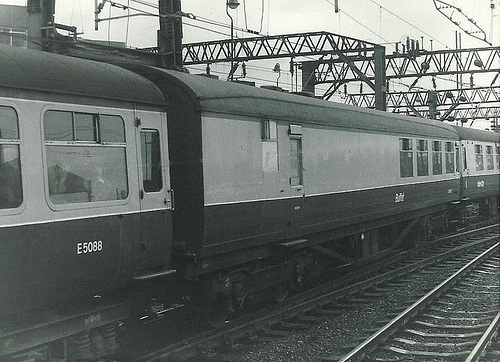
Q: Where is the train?
A: To the left.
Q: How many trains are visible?
A: One.